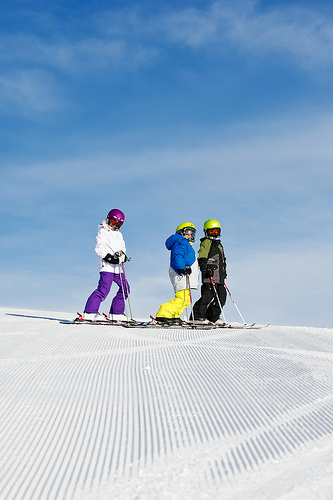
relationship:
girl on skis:
[82, 208, 132, 323] [75, 314, 269, 331]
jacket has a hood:
[95, 222, 129, 274] [97, 218, 111, 230]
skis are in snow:
[75, 314, 269, 331] [0, 308, 333, 499]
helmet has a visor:
[108, 209, 125, 229] [108, 216, 124, 230]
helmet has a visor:
[204, 219, 223, 233] [206, 228, 222, 236]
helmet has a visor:
[179, 221, 197, 235] [184, 227, 196, 242]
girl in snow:
[82, 208, 132, 323] [0, 308, 333, 499]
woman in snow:
[156, 222, 202, 323] [0, 308, 333, 499]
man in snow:
[189, 219, 228, 323] [0, 308, 333, 499]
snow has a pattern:
[0, 308, 333, 499] [5, 329, 332, 497]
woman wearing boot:
[156, 222, 202, 323] [155, 317, 171, 325]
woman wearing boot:
[156, 222, 202, 323] [176, 317, 188, 325]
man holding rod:
[189, 219, 228, 323] [211, 276, 230, 325]